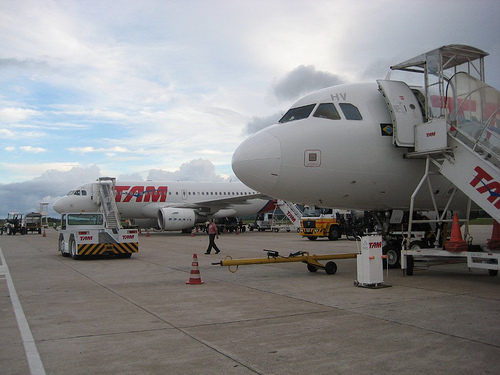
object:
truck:
[299, 204, 367, 241]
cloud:
[0, 0, 500, 216]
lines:
[0, 252, 58, 375]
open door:
[92, 180, 99, 203]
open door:
[375, 79, 432, 148]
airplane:
[51, 175, 301, 233]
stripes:
[75, 241, 139, 255]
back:
[59, 212, 140, 260]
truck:
[55, 209, 139, 261]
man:
[204, 218, 221, 255]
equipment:
[211, 249, 387, 276]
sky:
[3, 10, 497, 227]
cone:
[486, 221, 500, 251]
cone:
[446, 213, 468, 253]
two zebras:
[108, 182, 172, 202]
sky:
[0, 4, 500, 211]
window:
[339, 102, 364, 120]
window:
[313, 103, 341, 120]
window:
[278, 103, 316, 123]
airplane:
[233, 73, 499, 269]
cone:
[185, 253, 204, 285]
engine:
[156, 204, 207, 231]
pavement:
[0, 277, 496, 372]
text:
[114, 185, 169, 202]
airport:
[26, 42, 474, 373]